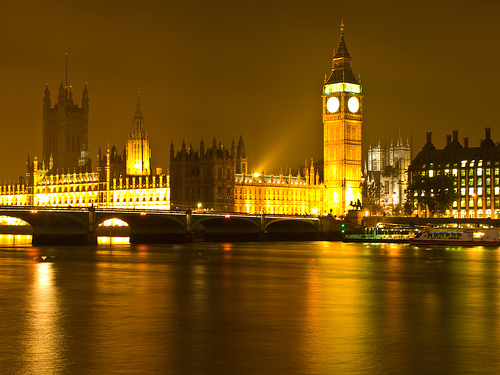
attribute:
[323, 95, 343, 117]
clock — small, white, on, round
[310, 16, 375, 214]
tower — high, orange, long, tall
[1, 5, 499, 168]
sky — orange, black, open, big, clear, grey, foggy, close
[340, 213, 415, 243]
boat — White 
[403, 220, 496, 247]
boat — red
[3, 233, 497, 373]
water — brown, close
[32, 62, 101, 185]
building — tall 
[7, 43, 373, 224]
building — castle shaped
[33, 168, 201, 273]
arch — tall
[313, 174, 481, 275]
light — green